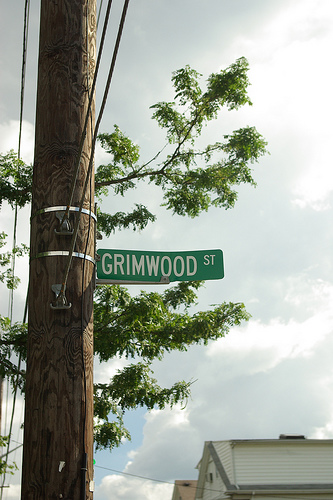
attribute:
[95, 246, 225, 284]
sign — green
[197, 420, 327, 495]
house — white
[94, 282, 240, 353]
limb — green 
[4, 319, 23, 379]
limb — green 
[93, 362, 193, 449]
limb — green 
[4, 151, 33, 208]
limb — green 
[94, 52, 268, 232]
limb — green 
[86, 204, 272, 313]
sign — street sign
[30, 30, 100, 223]
post — brown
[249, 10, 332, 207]
cloud — white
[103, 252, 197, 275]
lettering — white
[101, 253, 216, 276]
writing — white